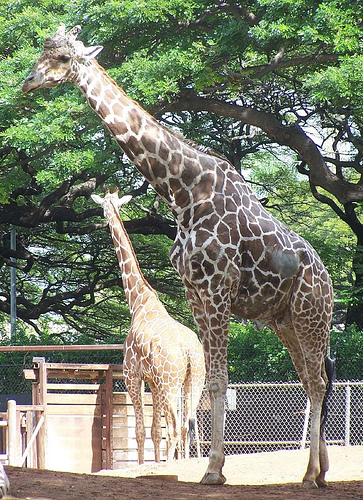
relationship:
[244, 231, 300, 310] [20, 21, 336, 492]
patch on giraffe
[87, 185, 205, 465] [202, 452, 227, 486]
giraffe has foot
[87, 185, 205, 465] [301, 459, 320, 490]
giraffe has foot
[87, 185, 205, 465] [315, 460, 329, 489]
giraffe has foot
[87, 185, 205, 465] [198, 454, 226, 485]
giraffe has foot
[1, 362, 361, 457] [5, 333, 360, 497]
fence around enclosure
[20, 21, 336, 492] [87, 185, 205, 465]
giraffe near giraffe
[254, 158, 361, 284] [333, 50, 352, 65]
tree has leaf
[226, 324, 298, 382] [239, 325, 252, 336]
tree has leaf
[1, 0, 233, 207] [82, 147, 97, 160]
tree has leaf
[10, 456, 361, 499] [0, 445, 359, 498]
shadow on ground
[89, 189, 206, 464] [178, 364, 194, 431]
giraffe has tail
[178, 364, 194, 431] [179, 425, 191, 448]
tail has hair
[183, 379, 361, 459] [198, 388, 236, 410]
fence has sticker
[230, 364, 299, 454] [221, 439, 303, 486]
fence behind dirt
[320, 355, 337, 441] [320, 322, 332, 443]
black hair on giraffe tail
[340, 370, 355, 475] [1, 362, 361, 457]
rails on fence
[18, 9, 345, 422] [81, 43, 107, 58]
giraffe has ear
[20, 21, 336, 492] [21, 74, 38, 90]
giraffe has nose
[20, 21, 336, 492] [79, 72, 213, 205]
giraffe has neck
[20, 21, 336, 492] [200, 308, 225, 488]
giraffe has leg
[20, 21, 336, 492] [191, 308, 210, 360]
giraffe has leg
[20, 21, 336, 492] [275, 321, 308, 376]
giraffe has leg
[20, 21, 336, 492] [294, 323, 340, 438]
giraffe has leg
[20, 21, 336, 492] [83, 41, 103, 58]
giraffe has ear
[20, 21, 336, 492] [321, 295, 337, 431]
giraffe has tail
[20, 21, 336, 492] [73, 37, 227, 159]
giraffe has mane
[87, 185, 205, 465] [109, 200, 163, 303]
giraffe has mane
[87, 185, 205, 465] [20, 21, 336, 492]
giraffe standing near giraffe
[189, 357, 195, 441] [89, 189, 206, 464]
tail on giraffe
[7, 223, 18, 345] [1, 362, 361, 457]
pole behind fence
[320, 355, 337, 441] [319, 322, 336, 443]
black hair on giraffe tail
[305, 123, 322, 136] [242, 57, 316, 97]
sky showing through branches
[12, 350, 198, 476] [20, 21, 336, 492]
fence sneer giraffe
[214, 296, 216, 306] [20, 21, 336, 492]
fur on giraffe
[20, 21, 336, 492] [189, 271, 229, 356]
giraffe with spots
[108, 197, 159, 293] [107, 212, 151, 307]
mane on neck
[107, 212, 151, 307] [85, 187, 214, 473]
neck of giraffe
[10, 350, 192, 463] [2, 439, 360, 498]
structure behind dirt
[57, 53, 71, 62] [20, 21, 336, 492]
eye of giraffe